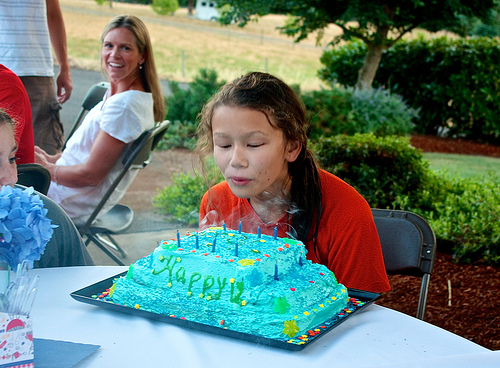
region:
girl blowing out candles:
[83, 70, 472, 345]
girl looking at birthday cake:
[64, 71, 426, 346]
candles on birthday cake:
[164, 214, 315, 287]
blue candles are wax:
[165, 213, 312, 283]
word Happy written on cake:
[151, 253, 253, 308]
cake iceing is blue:
[101, 218, 353, 330]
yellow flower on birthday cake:
[271, 310, 305, 342]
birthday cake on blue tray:
[78, 218, 383, 355]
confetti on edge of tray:
[297, 303, 373, 336]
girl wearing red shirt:
[188, 102, 401, 302]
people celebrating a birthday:
[0, 5, 483, 360]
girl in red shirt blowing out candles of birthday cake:
[71, 74, 431, 348]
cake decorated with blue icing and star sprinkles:
[102, 219, 357, 357]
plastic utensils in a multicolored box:
[0, 260, 40, 366]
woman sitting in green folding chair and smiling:
[43, 16, 164, 229]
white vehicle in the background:
[180, 1, 255, 32]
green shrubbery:
[312, 35, 499, 141]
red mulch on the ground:
[441, 261, 498, 335]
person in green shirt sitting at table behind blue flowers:
[0, 110, 90, 270]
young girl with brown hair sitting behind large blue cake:
[70, 70, 390, 349]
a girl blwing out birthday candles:
[143, 73, 395, 327]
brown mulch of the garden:
[449, 279, 489, 333]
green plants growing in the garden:
[391, 161, 498, 264]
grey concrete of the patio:
[121, 230, 153, 265]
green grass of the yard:
[443, 153, 488, 185]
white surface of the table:
[117, 326, 181, 364]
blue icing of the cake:
[189, 295, 251, 322]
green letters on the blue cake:
[158, 257, 245, 304]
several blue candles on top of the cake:
[167, 215, 271, 252]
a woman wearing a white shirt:
[53, 22, 163, 224]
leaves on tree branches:
[218, 0, 482, 48]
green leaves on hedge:
[325, 37, 497, 137]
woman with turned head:
[36, 14, 162, 211]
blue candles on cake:
[174, 221, 303, 281]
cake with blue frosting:
[110, 226, 347, 339]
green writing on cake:
[153, 256, 243, 305]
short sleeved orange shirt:
[201, 167, 389, 296]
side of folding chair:
[81, 117, 171, 264]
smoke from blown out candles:
[203, 199, 303, 226]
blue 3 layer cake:
[118, 206, 324, 336]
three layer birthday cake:
[45, 180, 407, 345]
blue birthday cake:
[55, 200, 375, 350]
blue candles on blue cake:
[154, 210, 319, 292]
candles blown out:
[146, 199, 315, 289]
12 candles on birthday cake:
[141, 211, 301, 300]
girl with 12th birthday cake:
[79, 51, 426, 356]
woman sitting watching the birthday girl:
[11, 8, 174, 242]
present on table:
[0, 308, 46, 365]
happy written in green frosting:
[122, 251, 254, 316]